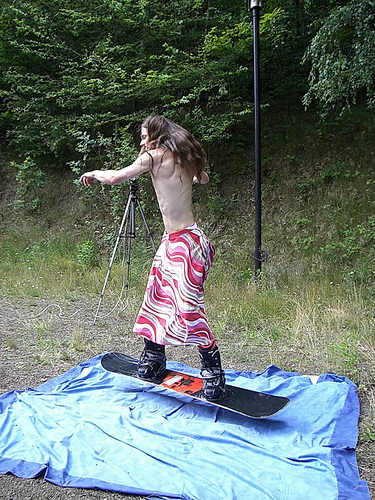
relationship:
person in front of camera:
[77, 113, 226, 397] [93, 177, 157, 325]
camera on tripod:
[93, 177, 157, 325] [90, 197, 159, 325]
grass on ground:
[2, 235, 375, 390] [0, 123, 374, 497]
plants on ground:
[1, 130, 374, 270] [0, 123, 374, 497]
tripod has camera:
[90, 197, 159, 325] [93, 177, 157, 325]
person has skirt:
[77, 113, 226, 397] [130, 223, 218, 348]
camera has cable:
[93, 177, 157, 325] [17, 227, 131, 319]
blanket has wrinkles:
[3, 353, 370, 498] [0, 350, 371, 498]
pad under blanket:
[301, 373, 320, 384] [3, 353, 370, 498]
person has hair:
[77, 113, 226, 397] [141, 112, 211, 184]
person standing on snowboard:
[77, 113, 226, 397] [100, 351, 290, 419]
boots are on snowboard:
[134, 338, 229, 401] [100, 351, 290, 419]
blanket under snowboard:
[3, 353, 370, 498] [100, 351, 290, 419]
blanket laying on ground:
[3, 353, 370, 498] [0, 123, 374, 497]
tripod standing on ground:
[90, 197, 159, 325] [0, 123, 374, 497]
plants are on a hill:
[1, 130, 374, 270] [0, 80, 373, 281]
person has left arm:
[77, 113, 226, 397] [76, 151, 154, 189]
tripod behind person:
[90, 197, 159, 325] [77, 113, 226, 397]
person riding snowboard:
[77, 113, 226, 397] [100, 351, 290, 419]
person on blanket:
[77, 113, 226, 397] [3, 353, 370, 498]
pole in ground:
[249, 0, 263, 288] [0, 123, 374, 497]